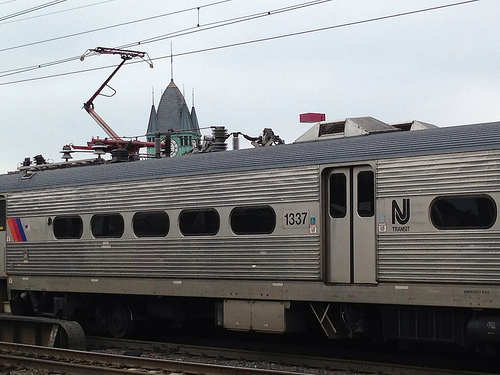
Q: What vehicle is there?
A: Train.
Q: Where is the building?
A: Background.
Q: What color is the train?
A: Gray.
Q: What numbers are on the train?
A: One three three seven.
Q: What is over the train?
A: Electric wires.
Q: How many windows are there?
A: Eight.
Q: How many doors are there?
A: Two.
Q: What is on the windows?
A: Tint.